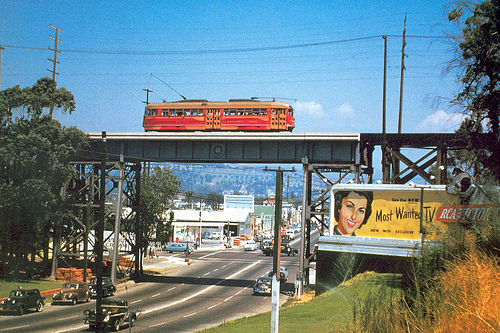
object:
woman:
[332, 190, 373, 237]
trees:
[0, 73, 96, 279]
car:
[1, 287, 46, 316]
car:
[51, 279, 90, 304]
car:
[86, 279, 117, 299]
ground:
[386, 191, 476, 244]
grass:
[437, 258, 497, 326]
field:
[206, 240, 500, 333]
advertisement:
[435, 198, 498, 225]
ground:
[383, 146, 421, 175]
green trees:
[0, 79, 94, 279]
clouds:
[294, 67, 471, 131]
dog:
[445, 168, 475, 197]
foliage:
[351, 223, 499, 333]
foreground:
[204, 271, 398, 332]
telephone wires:
[2, 24, 496, 89]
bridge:
[2, 131, 498, 296]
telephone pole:
[46, 27, 61, 124]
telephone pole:
[380, 35, 388, 132]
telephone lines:
[0, 34, 476, 58]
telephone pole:
[273, 172, 284, 278]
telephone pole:
[393, 16, 409, 134]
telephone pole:
[44, 22, 64, 121]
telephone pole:
[141, 88, 153, 104]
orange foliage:
[428, 244, 498, 330]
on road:
[0, 229, 316, 333]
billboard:
[317, 180, 496, 260]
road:
[0, 210, 311, 333]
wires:
[4, 27, 499, 89]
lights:
[347, 179, 355, 184]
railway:
[38, 122, 499, 267]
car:
[85, 298, 136, 331]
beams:
[87, 130, 361, 165]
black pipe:
[140, 95, 295, 133]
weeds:
[344, 246, 500, 333]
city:
[87, 164, 385, 205]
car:
[164, 242, 192, 253]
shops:
[155, 193, 264, 248]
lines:
[0, 225, 317, 331]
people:
[224, 111, 227, 115]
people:
[198, 111, 202, 116]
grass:
[281, 291, 363, 332]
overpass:
[90, 129, 473, 176]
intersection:
[167, 229, 315, 278]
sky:
[0, 0, 500, 134]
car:
[139, 96, 295, 133]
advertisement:
[330, 190, 464, 242]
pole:
[41, 23, 65, 122]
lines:
[0, 32, 482, 86]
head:
[452, 167, 467, 175]